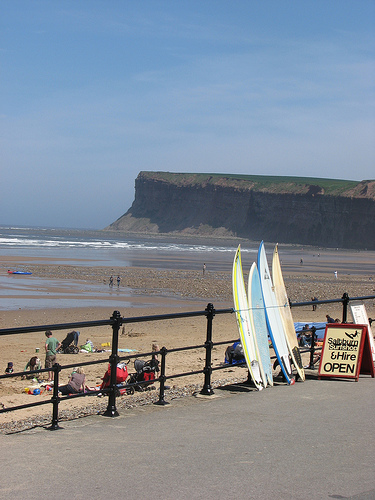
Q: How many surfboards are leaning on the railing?
A: 4.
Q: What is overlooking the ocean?
A: A bluff.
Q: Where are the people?
A: At the beach.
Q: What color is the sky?
A: Blue.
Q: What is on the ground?
A: Sand.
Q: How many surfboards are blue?
A: 2.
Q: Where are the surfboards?
A: Leaning against the rails.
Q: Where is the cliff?
A: Background.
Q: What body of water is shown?
A: Ocean.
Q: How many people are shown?
A: More than 5.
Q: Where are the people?
A: On the sand.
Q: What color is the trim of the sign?
A: Red.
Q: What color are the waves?
A: White.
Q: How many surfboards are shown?
A: 4.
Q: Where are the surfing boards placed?
A: Leaning in the fence.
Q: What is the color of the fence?
A: Black.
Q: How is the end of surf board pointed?
A: Up.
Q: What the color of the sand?
A: Light brown.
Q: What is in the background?
A: Cliff and see.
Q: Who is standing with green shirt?
A: A boy.